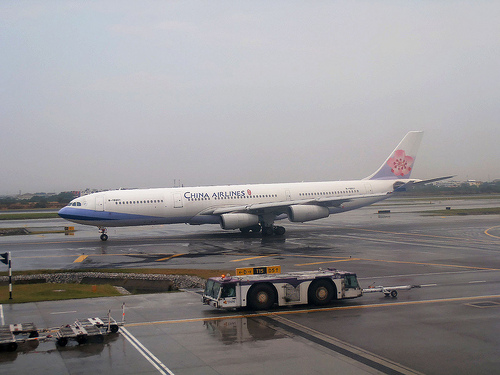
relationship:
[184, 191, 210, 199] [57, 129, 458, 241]
writing on plane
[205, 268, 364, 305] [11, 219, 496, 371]
truck on ground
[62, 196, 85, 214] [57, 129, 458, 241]
cockpit of plane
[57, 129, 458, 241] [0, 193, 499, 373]
plane reflected on ground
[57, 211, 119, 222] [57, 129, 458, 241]
line on bottom of plane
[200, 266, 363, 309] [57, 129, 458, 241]
truck behind plane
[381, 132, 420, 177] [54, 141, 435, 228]
vertical stabilizer on jet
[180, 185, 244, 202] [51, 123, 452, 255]
writing on plane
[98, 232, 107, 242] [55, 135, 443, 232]
landing gear on plane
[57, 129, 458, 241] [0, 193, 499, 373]
plane on ground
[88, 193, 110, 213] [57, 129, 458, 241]
door on plane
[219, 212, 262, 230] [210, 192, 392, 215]
jet engine mounted to plane wing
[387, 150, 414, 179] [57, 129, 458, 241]
flower on plane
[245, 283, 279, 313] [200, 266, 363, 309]
wheel on truck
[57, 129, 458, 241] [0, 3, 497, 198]
plane against sky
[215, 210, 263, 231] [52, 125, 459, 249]
jet engine on jet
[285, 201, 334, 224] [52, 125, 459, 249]
jet engine on jet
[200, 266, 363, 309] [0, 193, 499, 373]
truck on ground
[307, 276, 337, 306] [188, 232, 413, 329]
wheel on truck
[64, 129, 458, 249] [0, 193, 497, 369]
plane on ground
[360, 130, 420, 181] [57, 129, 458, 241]
vertical stabilizer of plane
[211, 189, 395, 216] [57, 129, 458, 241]
plane wing of plane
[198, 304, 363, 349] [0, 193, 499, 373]
reflection on ground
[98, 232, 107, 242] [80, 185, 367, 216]
landing gear on jet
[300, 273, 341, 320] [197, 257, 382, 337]
wheel on truck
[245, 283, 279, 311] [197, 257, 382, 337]
wheel on truck